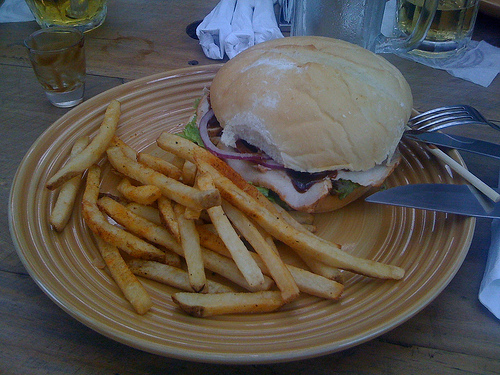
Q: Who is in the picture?
A: No one.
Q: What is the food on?
A: A plate.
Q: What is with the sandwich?
A: French fries.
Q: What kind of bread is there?
A: Roll.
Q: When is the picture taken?
A: Day time.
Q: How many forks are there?
A: One.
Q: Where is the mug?
A: Above plate.